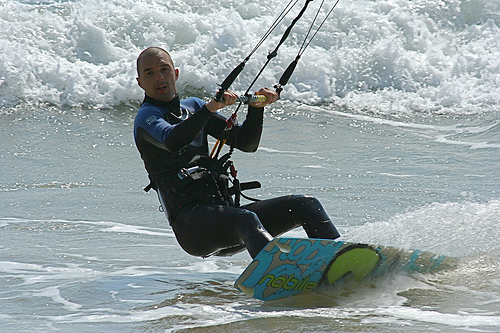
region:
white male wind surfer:
[110, 0, 371, 284]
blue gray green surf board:
[221, 225, 477, 304]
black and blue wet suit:
[119, 88, 350, 270]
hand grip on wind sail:
[206, 83, 286, 110]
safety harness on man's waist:
[142, 113, 249, 212]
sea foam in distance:
[3, 2, 498, 129]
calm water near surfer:
[5, 111, 498, 331]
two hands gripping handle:
[211, 85, 282, 113]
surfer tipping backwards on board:
[128, 41, 470, 288]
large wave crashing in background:
[1, 3, 497, 116]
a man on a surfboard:
[111, 40, 459, 307]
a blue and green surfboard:
[241, 233, 467, 321]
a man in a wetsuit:
[126, 33, 398, 280]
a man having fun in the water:
[131, 20, 464, 322]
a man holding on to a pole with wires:
[208, 24, 327, 122]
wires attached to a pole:
[221, 0, 359, 89]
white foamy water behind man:
[22, 5, 497, 113]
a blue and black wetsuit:
[109, 85, 361, 255]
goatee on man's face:
[151, 71, 180, 111]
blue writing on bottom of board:
[258, 243, 349, 303]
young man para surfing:
[117, 54, 318, 260]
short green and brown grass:
[17, 24, 74, 84]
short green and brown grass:
[42, 149, 115, 199]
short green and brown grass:
[362, 105, 409, 143]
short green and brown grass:
[69, 22, 129, 112]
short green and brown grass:
[371, 106, 478, 193]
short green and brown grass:
[341, 178, 394, 231]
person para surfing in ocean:
[112, 43, 258, 243]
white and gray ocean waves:
[12, 121, 67, 178]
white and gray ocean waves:
[44, 192, 94, 272]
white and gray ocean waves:
[90, 252, 124, 280]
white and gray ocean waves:
[35, 43, 76, 112]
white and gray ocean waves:
[342, 48, 402, 122]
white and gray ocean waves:
[389, 44, 469, 120]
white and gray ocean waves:
[20, 184, 94, 252]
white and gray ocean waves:
[93, 14, 170, 40]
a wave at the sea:
[54, 16, 114, 62]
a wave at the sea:
[332, 48, 404, 104]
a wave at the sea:
[192, 22, 234, 54]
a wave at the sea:
[379, 49, 435, 98]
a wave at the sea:
[349, 30, 391, 80]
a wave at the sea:
[83, 36, 107, 92]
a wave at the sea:
[16, 15, 59, 79]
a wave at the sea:
[400, 209, 446, 318]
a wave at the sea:
[148, 268, 186, 304]